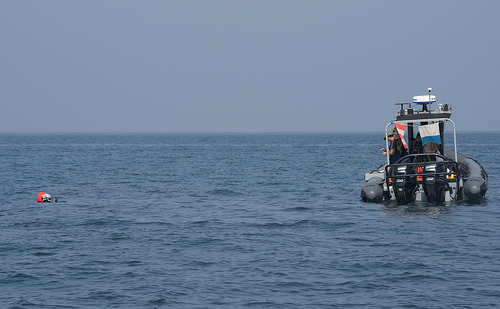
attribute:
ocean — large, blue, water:
[1, 132, 498, 308]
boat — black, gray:
[360, 88, 488, 203]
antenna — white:
[412, 94, 434, 111]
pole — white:
[385, 117, 456, 161]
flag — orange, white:
[391, 122, 406, 151]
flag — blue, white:
[418, 122, 442, 148]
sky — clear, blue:
[1, 0, 499, 131]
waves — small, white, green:
[247, 218, 358, 231]